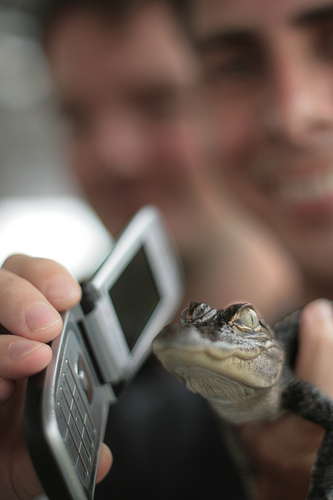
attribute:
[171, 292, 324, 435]
snake — brown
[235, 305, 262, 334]
eyes — yellow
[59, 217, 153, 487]
cellphone — grey, black, flip, silver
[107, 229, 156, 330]
screen — off, lcd, black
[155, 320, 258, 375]
mouth — closed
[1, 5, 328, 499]
picture — daytime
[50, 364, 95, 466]
controls — grey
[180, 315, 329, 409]
alligator — held, baby, tiny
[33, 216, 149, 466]
phone — silver, flip, open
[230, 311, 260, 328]
eye — green, large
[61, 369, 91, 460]
buttons — numbered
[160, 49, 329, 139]
faces — blurry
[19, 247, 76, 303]
finger — pointer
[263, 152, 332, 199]
smile — white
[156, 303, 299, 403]
frog — held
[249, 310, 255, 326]
slit — black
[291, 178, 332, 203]
teeth — exposed